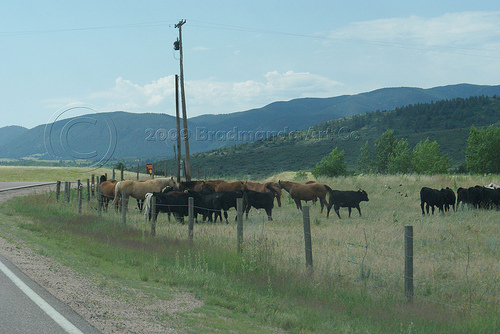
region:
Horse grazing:
[267, 173, 334, 210]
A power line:
[170, 15, 190, 170]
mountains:
[6, 90, 171, 161]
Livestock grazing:
[102, 178, 498, 233]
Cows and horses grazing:
[99, 168, 389, 235]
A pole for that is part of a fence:
[394, 220, 435, 310]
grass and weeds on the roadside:
[168, 235, 265, 305]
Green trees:
[358, 125, 453, 179]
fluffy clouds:
[187, 73, 342, 102]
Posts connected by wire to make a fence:
[298, 207, 431, 299]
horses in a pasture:
[115, 158, 417, 238]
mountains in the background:
[46, 95, 498, 177]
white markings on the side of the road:
[0, 257, 90, 329]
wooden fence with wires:
[75, 179, 470, 313]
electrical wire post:
[153, 24, 248, 191]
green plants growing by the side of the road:
[67, 206, 334, 317]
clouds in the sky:
[62, 23, 398, 123]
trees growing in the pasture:
[290, 109, 499, 196]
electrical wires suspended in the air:
[131, 20, 498, 75]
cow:
[314, 165, 386, 237]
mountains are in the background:
[22, 20, 497, 231]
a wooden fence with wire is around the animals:
[53, 160, 481, 332]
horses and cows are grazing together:
[98, 172, 498, 222]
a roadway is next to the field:
[1, 164, 113, 332]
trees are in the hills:
[268, 98, 498, 174]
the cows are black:
[148, 180, 499, 225]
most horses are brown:
[181, 175, 335, 209]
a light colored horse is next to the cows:
[110, 168, 178, 223]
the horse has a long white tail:
[111, 176, 123, 213]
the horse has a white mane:
[154, 170, 174, 186]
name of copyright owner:
[23, 91, 402, 178]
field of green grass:
[18, 166, 495, 328]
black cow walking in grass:
[321, 181, 376, 216]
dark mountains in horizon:
[46, 98, 206, 170]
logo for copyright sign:
[36, 97, 123, 177]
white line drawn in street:
[3, 271, 82, 331]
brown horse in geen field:
[272, 171, 339, 219]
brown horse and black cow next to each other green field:
[273, 172, 378, 222]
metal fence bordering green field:
[63, 177, 498, 303]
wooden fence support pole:
[295, 203, 325, 288]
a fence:
[134, 176, 407, 319]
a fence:
[351, 214, 449, 276]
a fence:
[376, 205, 452, 331]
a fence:
[280, 171, 442, 325]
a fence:
[305, 139, 399, 290]